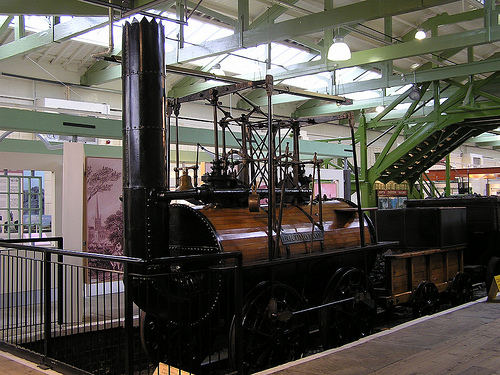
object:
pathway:
[243, 295, 500, 375]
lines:
[292, 351, 330, 364]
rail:
[0, 235, 147, 375]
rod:
[48, 260, 125, 275]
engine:
[319, 265, 380, 350]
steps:
[409, 148, 443, 157]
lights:
[326, 33, 352, 62]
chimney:
[120, 13, 174, 257]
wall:
[0, 74, 500, 246]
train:
[121, 183, 500, 373]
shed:
[164, 72, 363, 211]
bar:
[78, 0, 456, 87]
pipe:
[120, 15, 171, 279]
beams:
[168, 22, 500, 103]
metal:
[122, 181, 165, 224]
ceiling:
[150, 0, 500, 78]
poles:
[43, 251, 52, 356]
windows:
[178, 0, 242, 53]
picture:
[87, 164, 125, 283]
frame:
[81, 155, 123, 284]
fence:
[217, 113, 302, 191]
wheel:
[227, 278, 313, 375]